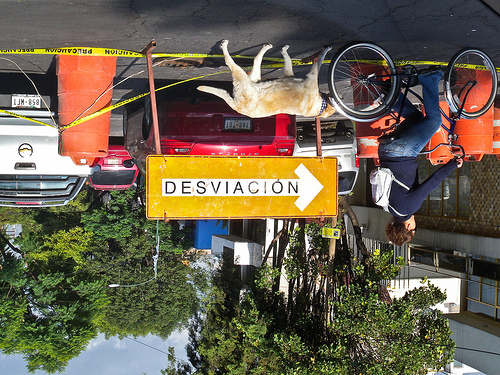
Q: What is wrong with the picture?
A: It's upside down.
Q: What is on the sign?
A: Arrow and the word "Desviacion".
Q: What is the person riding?
A: Bicycle.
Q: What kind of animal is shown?
A: Dog.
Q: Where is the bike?
A: By the dog.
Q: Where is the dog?
A: By the bike.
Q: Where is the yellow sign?
A: Behind the dog.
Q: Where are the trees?
A: Behind the cars.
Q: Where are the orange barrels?
A: In the road.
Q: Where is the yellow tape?
A: By the orange barrels.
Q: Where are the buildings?
A: Side of the road.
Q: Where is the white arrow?
A: On the yellow sign.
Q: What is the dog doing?
A: Following the bike.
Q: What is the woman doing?
A: Riding a bike.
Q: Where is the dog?
A: Behind the bike.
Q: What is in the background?
A: Trees.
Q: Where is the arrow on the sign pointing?
A: To the right.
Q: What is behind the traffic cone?
A: Cars.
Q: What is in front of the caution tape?
A: A yellow sign with an arrow.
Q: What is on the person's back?
A: A backpack.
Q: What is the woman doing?
A: Riding a bike.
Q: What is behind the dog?
A: A small red sedan.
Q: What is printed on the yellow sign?
A: Desviacion.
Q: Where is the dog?
A: By the bike.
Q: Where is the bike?
A: By the dog.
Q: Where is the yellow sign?
A: By the dog.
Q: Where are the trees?
A: Behind the yellow sign.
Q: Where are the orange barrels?
A: By the yellow tape.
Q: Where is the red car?
A: Behind the yellow sign.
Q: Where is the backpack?
A: On the biker.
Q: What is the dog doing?
A: Following the bike.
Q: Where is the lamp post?
A: By the trees.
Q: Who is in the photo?
A: Person riding bicycle.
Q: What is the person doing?
A: Riding bike.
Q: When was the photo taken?
A: Sunny day.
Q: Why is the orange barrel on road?
A: To block traffic.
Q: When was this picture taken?
A: Daytime.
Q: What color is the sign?
A: Yellow.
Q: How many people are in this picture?
A: 1.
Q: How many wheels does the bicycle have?
A: 2.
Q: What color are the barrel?
A: Orange.